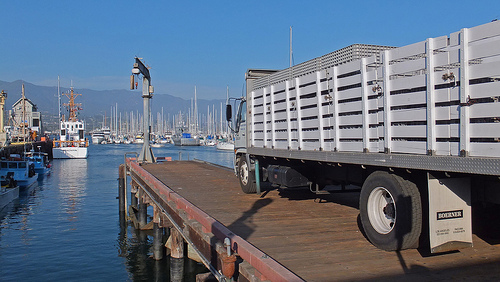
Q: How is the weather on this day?
A: It is clear.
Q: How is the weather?
A: It is clear.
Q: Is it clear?
A: Yes, it is clear.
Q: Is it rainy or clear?
A: It is clear.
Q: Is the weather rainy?
A: No, it is clear.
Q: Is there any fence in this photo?
A: No, there are no fences.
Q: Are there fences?
A: No, there are no fences.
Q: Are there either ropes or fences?
A: No, there are no fences or ropes.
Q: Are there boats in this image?
A: Yes, there is a boat.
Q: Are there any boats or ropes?
A: Yes, there is a boat.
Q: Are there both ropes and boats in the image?
A: No, there is a boat but no ropes.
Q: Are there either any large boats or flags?
A: Yes, there is a large boat.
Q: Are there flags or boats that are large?
A: Yes, the boat is large.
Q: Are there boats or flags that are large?
A: Yes, the boat is large.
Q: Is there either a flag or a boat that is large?
A: Yes, the boat is large.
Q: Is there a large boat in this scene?
A: Yes, there is a large boat.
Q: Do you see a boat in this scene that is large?
A: Yes, there is a boat that is large.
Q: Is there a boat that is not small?
A: Yes, there is a large boat.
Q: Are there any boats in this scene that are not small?
A: Yes, there is a large boat.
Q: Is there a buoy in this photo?
A: No, there are no buoys.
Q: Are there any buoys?
A: No, there are no buoys.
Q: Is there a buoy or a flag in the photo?
A: No, there are no buoys or flags.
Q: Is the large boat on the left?
A: Yes, the boat is on the left of the image.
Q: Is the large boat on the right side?
A: No, the boat is on the left of the image.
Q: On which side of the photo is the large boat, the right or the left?
A: The boat is on the left of the image.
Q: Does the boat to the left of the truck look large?
A: Yes, the boat is large.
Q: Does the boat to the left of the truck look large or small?
A: The boat is large.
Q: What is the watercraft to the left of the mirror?
A: The watercraft is a boat.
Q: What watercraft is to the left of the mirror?
A: The watercraft is a boat.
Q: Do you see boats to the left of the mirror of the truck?
A: Yes, there is a boat to the left of the mirror.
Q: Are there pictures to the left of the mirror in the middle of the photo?
A: No, there is a boat to the left of the mirror.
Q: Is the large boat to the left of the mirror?
A: Yes, the boat is to the left of the mirror.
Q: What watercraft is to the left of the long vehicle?
A: The watercraft is a boat.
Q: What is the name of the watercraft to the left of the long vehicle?
A: The watercraft is a boat.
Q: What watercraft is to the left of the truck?
A: The watercraft is a boat.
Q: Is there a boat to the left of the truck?
A: Yes, there is a boat to the left of the truck.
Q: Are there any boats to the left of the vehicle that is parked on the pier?
A: Yes, there is a boat to the left of the truck.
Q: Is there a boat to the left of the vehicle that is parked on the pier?
A: Yes, there is a boat to the left of the truck.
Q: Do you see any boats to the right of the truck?
A: No, the boat is to the left of the truck.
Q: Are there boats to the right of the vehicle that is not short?
A: No, the boat is to the left of the truck.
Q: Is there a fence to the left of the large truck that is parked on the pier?
A: No, there is a boat to the left of the truck.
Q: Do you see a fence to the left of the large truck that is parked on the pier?
A: No, there is a boat to the left of the truck.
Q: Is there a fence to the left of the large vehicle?
A: No, there is a boat to the left of the truck.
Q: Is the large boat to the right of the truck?
A: No, the boat is to the left of the truck.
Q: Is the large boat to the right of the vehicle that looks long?
A: No, the boat is to the left of the truck.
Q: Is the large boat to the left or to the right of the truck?
A: The boat is to the left of the truck.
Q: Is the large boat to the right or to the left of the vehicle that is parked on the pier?
A: The boat is to the left of the truck.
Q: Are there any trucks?
A: Yes, there is a truck.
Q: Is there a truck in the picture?
A: Yes, there is a truck.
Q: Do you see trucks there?
A: Yes, there is a truck.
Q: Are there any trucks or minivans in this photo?
A: Yes, there is a truck.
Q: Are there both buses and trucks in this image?
A: No, there is a truck but no buses.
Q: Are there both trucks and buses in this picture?
A: No, there is a truck but no buses.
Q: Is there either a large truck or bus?
A: Yes, there is a large truck.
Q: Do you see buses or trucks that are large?
A: Yes, the truck is large.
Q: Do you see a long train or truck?
A: Yes, there is a long truck.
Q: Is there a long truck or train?
A: Yes, there is a long truck.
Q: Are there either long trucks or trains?
A: Yes, there is a long truck.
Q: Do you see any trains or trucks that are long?
A: Yes, the truck is long.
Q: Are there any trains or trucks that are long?
A: Yes, the truck is long.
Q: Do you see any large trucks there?
A: Yes, there is a large truck.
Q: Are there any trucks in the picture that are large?
A: Yes, there is a truck that is large.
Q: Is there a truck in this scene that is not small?
A: Yes, there is a large truck.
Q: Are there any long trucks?
A: Yes, there is a long truck.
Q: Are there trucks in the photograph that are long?
A: Yes, there is a truck that is long.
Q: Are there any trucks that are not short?
A: Yes, there is a long truck.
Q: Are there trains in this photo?
A: No, there are no trains.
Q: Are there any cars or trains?
A: No, there are no trains or cars.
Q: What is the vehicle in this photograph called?
A: The vehicle is a truck.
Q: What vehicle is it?
A: The vehicle is a truck.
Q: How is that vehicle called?
A: This is a truck.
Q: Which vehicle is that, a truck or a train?
A: This is a truck.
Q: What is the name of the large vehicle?
A: The vehicle is a truck.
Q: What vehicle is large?
A: The vehicle is a truck.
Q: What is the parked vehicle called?
A: The vehicle is a truck.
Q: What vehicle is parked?
A: The vehicle is a truck.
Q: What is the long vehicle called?
A: The vehicle is a truck.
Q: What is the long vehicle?
A: The vehicle is a truck.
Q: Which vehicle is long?
A: The vehicle is a truck.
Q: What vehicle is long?
A: The vehicle is a truck.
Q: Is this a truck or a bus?
A: This is a truck.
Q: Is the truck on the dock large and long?
A: Yes, the truck is large and long.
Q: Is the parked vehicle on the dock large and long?
A: Yes, the truck is large and long.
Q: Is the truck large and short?
A: No, the truck is large but long.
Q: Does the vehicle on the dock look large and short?
A: No, the truck is large but long.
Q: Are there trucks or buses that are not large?
A: No, there is a truck but it is large.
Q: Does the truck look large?
A: Yes, the truck is large.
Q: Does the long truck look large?
A: Yes, the truck is large.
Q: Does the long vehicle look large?
A: Yes, the truck is large.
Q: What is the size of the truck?
A: The truck is large.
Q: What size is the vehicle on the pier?
A: The truck is large.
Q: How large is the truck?
A: The truck is large.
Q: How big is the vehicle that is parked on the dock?
A: The truck is large.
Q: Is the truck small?
A: No, the truck is large.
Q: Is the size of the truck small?
A: No, the truck is large.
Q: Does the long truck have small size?
A: No, the truck is large.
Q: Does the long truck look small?
A: No, the truck is large.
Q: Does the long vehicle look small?
A: No, the truck is large.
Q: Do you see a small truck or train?
A: No, there is a truck but it is large.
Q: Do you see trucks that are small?
A: No, there is a truck but it is large.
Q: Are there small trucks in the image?
A: No, there is a truck but it is large.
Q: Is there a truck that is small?
A: No, there is a truck but it is large.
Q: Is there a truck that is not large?
A: No, there is a truck but it is large.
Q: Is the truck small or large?
A: The truck is large.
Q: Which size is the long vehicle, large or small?
A: The truck is large.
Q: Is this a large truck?
A: Yes, this is a large truck.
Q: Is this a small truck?
A: No, this is a large truck.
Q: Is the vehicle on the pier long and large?
A: Yes, the truck is long and large.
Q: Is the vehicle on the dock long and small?
A: No, the truck is long but large.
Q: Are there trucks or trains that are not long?
A: No, there is a truck but it is long.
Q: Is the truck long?
A: Yes, the truck is long.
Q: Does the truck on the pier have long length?
A: Yes, the truck is long.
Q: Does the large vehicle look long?
A: Yes, the truck is long.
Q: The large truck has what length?
A: The truck is long.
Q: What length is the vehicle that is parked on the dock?
A: The truck is long.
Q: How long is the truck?
A: The truck is long.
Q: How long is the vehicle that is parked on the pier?
A: The truck is long.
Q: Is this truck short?
A: No, the truck is long.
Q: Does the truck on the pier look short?
A: No, the truck is long.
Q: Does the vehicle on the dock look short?
A: No, the truck is long.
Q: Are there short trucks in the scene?
A: No, there is a truck but it is long.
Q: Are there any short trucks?
A: No, there is a truck but it is long.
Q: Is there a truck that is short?
A: No, there is a truck but it is long.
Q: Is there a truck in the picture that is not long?
A: No, there is a truck but it is long.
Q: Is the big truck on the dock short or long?
A: The truck is long.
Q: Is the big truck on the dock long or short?
A: The truck is long.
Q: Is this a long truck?
A: Yes, this is a long truck.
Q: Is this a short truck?
A: No, this is a long truck.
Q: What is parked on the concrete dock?
A: The truck is parked on the dock.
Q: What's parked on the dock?
A: The truck is parked on the dock.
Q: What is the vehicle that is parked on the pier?
A: The vehicle is a truck.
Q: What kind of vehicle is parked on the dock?
A: The vehicle is a truck.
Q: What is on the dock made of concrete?
A: The truck is on the dock.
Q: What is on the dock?
A: The truck is on the dock.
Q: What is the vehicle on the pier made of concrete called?
A: The vehicle is a truck.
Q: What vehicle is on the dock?
A: The vehicle is a truck.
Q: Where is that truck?
A: The truck is on the pier.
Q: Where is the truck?
A: The truck is on the pier.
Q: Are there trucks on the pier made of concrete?
A: Yes, there is a truck on the pier.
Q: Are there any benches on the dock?
A: No, there is a truck on the dock.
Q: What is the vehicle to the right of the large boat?
A: The vehicle is a truck.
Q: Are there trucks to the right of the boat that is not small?
A: Yes, there is a truck to the right of the boat.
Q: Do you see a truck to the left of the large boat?
A: No, the truck is to the right of the boat.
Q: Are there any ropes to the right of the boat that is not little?
A: No, there is a truck to the right of the boat.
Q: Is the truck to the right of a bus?
A: No, the truck is to the right of the boat.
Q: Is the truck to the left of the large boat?
A: No, the truck is to the right of the boat.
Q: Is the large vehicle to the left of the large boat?
A: No, the truck is to the right of the boat.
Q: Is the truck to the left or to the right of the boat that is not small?
A: The truck is to the right of the boat.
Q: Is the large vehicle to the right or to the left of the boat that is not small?
A: The truck is to the right of the boat.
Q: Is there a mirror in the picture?
A: Yes, there is a mirror.